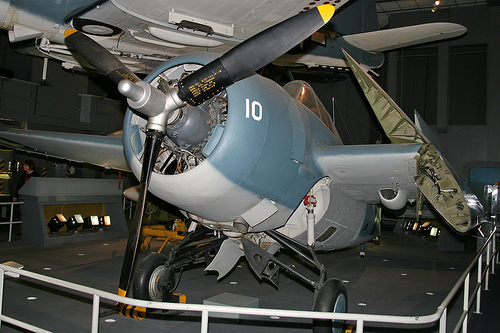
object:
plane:
[0, 5, 488, 332]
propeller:
[63, 4, 336, 299]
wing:
[316, 45, 489, 236]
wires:
[419, 146, 457, 199]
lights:
[47, 207, 112, 234]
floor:
[1, 219, 499, 333]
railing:
[0, 226, 498, 332]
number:
[244, 97, 262, 120]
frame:
[158, 194, 326, 313]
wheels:
[308, 278, 350, 333]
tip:
[317, 1, 336, 23]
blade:
[179, 4, 334, 108]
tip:
[63, 27, 77, 37]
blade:
[62, 27, 141, 84]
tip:
[116, 287, 127, 297]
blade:
[116, 127, 166, 298]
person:
[12, 161, 41, 202]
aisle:
[442, 224, 499, 331]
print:
[187, 68, 223, 98]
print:
[114, 67, 140, 85]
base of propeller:
[178, 57, 234, 109]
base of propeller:
[104, 65, 142, 84]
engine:
[122, 53, 300, 230]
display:
[1, 3, 498, 332]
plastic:
[281, 78, 344, 145]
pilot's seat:
[307, 102, 320, 117]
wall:
[17, 176, 131, 251]